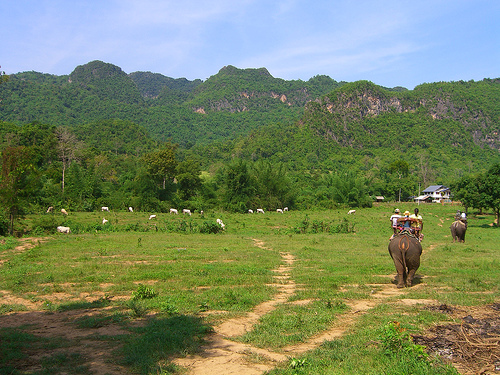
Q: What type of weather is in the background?
A: It is cloudy.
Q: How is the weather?
A: It is cloudy.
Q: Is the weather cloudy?
A: Yes, it is cloudy.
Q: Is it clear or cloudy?
A: It is cloudy.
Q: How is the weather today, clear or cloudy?
A: It is cloudy.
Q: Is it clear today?
A: No, it is cloudy.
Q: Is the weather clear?
A: No, it is cloudy.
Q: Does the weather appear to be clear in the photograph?
A: No, it is cloudy.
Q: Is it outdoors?
A: Yes, it is outdoors.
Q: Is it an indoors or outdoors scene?
A: It is outdoors.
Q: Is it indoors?
A: No, it is outdoors.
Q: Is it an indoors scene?
A: No, it is outdoors.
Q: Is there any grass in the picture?
A: Yes, there is grass.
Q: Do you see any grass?
A: Yes, there is grass.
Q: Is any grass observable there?
A: Yes, there is grass.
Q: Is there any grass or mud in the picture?
A: Yes, there is grass.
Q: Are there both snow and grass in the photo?
A: No, there is grass but no snow.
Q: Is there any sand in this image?
A: No, there is no sand.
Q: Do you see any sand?
A: No, there is no sand.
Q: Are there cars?
A: No, there are no cars.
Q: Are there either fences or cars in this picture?
A: No, there are no cars or fences.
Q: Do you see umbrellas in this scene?
A: No, there are no umbrellas.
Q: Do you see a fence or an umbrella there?
A: No, there are no umbrellas or fences.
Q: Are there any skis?
A: No, there are no skis.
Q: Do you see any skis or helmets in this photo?
A: No, there are no skis or helmets.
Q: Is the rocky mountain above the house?
A: Yes, the mountain is above the house.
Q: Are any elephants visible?
A: Yes, there is an elephant.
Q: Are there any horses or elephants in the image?
A: Yes, there is an elephant.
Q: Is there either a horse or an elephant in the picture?
A: Yes, there is an elephant.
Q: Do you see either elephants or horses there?
A: Yes, there is an elephant.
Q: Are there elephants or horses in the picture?
A: Yes, there is an elephant.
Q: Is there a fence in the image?
A: No, there are no fences.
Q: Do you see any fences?
A: No, there are no fences.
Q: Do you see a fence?
A: No, there are no fences.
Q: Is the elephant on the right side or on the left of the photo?
A: The elephant is on the right of the image.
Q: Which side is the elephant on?
A: The elephant is on the right of the image.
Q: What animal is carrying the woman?
A: The animal is an elephant.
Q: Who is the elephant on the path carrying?
A: The elephant is carrying a woman.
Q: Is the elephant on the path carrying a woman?
A: Yes, the elephant is carrying a woman.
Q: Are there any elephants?
A: Yes, there is an elephant.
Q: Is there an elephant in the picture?
A: Yes, there is an elephant.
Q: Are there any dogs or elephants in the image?
A: Yes, there is an elephant.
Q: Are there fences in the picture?
A: No, there are no fences.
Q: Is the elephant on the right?
A: Yes, the elephant is on the right of the image.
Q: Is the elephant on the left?
A: No, the elephant is on the right of the image.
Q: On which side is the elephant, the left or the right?
A: The elephant is on the right of the image.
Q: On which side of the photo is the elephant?
A: The elephant is on the right of the image.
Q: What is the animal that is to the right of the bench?
A: The animal is an elephant.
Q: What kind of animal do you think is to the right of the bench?
A: The animal is an elephant.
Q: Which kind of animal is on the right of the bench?
A: The animal is an elephant.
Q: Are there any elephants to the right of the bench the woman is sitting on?
A: Yes, there is an elephant to the right of the bench.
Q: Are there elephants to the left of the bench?
A: No, the elephant is to the right of the bench.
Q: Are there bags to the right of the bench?
A: No, there is an elephant to the right of the bench.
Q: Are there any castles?
A: No, there are no castles.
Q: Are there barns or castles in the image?
A: No, there are no castles or barns.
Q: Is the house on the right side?
A: Yes, the house is on the right of the image.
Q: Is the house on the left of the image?
A: No, the house is on the right of the image.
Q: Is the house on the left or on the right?
A: The house is on the right of the image.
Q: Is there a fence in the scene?
A: No, there are no fences.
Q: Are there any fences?
A: No, there are no fences.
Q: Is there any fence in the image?
A: No, there are no fences.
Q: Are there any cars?
A: No, there are no cars.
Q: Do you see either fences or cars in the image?
A: No, there are no cars or fences.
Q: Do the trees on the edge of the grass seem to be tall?
A: Yes, the trees are tall.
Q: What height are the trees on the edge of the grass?
A: The trees are tall.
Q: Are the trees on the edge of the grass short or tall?
A: The trees are tall.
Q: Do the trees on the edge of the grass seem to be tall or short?
A: The trees are tall.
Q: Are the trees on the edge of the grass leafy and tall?
A: Yes, the trees are leafy and tall.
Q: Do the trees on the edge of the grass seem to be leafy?
A: Yes, the trees are leafy.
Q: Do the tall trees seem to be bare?
A: No, the trees are leafy.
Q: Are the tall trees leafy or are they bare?
A: The trees are leafy.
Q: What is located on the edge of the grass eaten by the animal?
A: The trees are on the edge of the grass.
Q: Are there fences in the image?
A: No, there are no fences.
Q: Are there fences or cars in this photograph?
A: No, there are no fences or cars.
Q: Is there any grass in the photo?
A: Yes, there is grass.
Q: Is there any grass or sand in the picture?
A: Yes, there is grass.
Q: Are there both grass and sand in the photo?
A: No, there is grass but no sand.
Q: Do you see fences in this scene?
A: No, there are no fences.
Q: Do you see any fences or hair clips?
A: No, there are no fences or hair clips.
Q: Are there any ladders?
A: No, there are no ladders.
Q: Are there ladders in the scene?
A: No, there are no ladders.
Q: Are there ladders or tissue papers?
A: No, there are no ladders or tissue papers.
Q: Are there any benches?
A: Yes, there is a bench.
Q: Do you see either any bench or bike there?
A: Yes, there is a bench.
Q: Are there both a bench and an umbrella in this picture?
A: No, there is a bench but no umbrellas.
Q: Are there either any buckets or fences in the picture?
A: No, there are no fences or buckets.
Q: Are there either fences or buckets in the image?
A: No, there are no fences or buckets.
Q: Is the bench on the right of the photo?
A: Yes, the bench is on the right of the image.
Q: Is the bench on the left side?
A: No, the bench is on the right of the image.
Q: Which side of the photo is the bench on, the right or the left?
A: The bench is on the right of the image.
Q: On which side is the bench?
A: The bench is on the right of the image.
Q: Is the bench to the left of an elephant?
A: Yes, the bench is to the left of an elephant.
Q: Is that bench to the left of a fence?
A: No, the bench is to the left of an elephant.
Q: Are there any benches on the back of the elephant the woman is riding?
A: Yes, there is a bench on the back of the elephant.